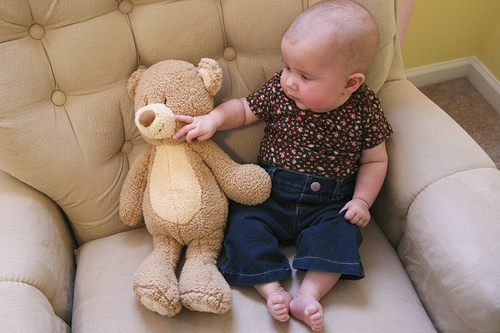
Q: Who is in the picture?
A: A baby.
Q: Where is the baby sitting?
A: Chair.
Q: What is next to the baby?
A: Teddy bear.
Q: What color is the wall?
A: Yellow.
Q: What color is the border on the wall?
A: White.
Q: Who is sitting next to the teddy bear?
A: Baby.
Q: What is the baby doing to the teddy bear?
A: Touching the nose.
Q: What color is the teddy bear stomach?
A: Yellow.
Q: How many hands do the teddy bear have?
A: 2.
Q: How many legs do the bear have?
A: 2.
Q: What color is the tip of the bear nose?
A: Brown.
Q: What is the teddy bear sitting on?
A: Chair.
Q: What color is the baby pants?
A: Blue.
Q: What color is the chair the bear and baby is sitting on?
A: Beige.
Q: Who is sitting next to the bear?
A: Baby.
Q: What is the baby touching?
A: Teddy bear.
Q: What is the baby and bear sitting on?
A: Chair.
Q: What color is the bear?
A: Tan.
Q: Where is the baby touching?
A: Bears face.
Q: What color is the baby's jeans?
A: Blue.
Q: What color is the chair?
A: Tan.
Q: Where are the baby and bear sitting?
A: Chair.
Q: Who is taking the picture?
A: Parent.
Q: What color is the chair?
A: Tan.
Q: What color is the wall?
A: Yellow.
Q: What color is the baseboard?
A: White.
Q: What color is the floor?
A: Brown.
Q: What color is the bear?
A: Brown.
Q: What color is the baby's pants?
A: Blue.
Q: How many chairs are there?
A: One.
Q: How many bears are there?
A: One.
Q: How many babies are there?
A: One.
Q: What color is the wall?
A: Yellow.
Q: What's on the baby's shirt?
A: Flowers.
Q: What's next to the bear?
A: A baby.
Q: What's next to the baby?
A: A bear.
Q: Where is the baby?
A: In a chair.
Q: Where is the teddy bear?
A: Next to the baby.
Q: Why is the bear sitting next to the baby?
A: For comfort.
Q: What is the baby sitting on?
A: A chair.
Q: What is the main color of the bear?
A: Light brown.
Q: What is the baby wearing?
A: A shirt and pants.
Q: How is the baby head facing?
A: To the left.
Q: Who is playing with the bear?
A: A baby.